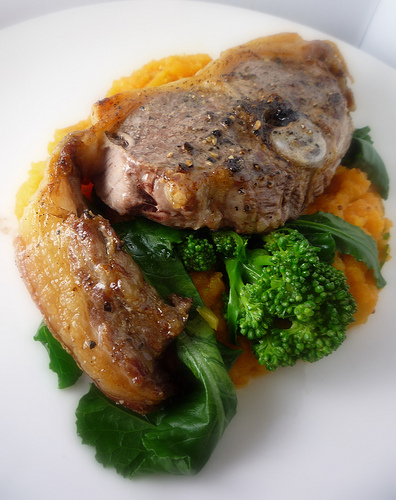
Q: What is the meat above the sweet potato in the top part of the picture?
A: The meat is a steak.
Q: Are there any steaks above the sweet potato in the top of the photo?
A: Yes, there is a steak above the sweet potato.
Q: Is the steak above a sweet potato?
A: Yes, the steak is above a sweet potato.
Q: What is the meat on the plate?
A: The meat is a steak.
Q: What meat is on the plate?
A: The meat is a steak.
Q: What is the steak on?
A: The steak is on the plate.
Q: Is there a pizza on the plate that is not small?
A: No, there is a steak on the plate.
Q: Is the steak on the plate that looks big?
A: Yes, the steak is on the plate.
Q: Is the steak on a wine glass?
A: No, the steak is on the plate.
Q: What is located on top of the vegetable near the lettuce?
A: The steak is on top of the broccoli.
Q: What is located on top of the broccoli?
A: The steak is on top of the broccoli.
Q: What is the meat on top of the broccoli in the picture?
A: The meat is a steak.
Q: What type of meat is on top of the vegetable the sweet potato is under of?
A: The meat is a steak.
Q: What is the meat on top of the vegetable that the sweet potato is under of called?
A: The meat is a steak.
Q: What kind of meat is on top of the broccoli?
A: The meat is a steak.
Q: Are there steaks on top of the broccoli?
A: Yes, there is a steak on top of the broccoli.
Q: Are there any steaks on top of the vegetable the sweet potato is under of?
A: Yes, there is a steak on top of the broccoli.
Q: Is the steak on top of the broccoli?
A: Yes, the steak is on top of the broccoli.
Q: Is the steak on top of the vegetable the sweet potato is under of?
A: Yes, the steak is on top of the broccoli.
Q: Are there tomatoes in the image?
A: No, there are no tomatoes.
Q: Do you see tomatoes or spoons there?
A: No, there are no tomatoes or spoons.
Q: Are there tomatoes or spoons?
A: No, there are no tomatoes or spoons.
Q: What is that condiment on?
A: The condiment is on the broccoli.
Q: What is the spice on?
A: The condiment is on the broccoli.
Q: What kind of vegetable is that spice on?
A: The spice is on the broccoli.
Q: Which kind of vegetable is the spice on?
A: The spice is on the broccoli.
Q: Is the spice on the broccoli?
A: Yes, the spice is on the broccoli.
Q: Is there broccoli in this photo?
A: Yes, there is broccoli.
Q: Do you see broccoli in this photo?
A: Yes, there is broccoli.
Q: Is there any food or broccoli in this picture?
A: Yes, there is broccoli.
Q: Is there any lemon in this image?
A: No, there are no lemons.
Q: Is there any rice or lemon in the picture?
A: No, there are no lemons or rice.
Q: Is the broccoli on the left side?
A: No, the broccoli is on the right of the image.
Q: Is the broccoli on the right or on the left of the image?
A: The broccoli is on the right of the image.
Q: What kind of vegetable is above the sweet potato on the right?
A: The vegetable is broccoli.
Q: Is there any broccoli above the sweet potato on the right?
A: Yes, there is broccoli above the sweet potato.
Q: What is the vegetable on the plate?
A: The vegetable is broccoli.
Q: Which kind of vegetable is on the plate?
A: The vegetable is broccoli.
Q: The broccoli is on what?
A: The broccoli is on the plate.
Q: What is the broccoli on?
A: The broccoli is on the plate.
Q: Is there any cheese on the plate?
A: No, there is broccoli on the plate.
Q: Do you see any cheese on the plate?
A: No, there is broccoli on the plate.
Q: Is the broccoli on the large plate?
A: Yes, the broccoli is on the plate.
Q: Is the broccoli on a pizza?
A: No, the broccoli is on the plate.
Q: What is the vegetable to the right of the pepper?
A: The vegetable is broccoli.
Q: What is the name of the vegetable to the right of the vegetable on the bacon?
A: The vegetable is broccoli.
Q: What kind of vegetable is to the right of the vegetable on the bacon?
A: The vegetable is broccoli.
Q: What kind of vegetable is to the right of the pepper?
A: The vegetable is broccoli.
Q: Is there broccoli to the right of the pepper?
A: Yes, there is broccoli to the right of the pepper.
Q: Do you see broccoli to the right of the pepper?
A: Yes, there is broccoli to the right of the pepper.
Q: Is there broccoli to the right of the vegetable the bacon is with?
A: Yes, there is broccoli to the right of the pepper.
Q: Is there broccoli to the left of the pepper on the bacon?
A: No, the broccoli is to the right of the pepper.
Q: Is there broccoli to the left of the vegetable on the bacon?
A: No, the broccoli is to the right of the pepper.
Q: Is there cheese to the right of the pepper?
A: No, there is broccoli to the right of the pepper.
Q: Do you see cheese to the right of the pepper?
A: No, there is broccoli to the right of the pepper.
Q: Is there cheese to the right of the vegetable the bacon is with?
A: No, there is broccoli to the right of the pepper.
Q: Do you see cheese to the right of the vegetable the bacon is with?
A: No, there is broccoli to the right of the pepper.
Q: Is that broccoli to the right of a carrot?
A: No, the broccoli is to the right of the pepper.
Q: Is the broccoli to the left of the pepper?
A: No, the broccoli is to the right of the pepper.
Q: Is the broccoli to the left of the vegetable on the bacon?
A: No, the broccoli is to the right of the pepper.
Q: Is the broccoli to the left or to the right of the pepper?
A: The broccoli is to the right of the pepper.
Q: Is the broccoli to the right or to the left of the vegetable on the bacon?
A: The broccoli is to the right of the pepper.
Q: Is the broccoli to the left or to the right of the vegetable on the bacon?
A: The broccoli is to the right of the pepper.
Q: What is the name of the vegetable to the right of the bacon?
A: The vegetable is broccoli.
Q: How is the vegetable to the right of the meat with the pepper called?
A: The vegetable is broccoli.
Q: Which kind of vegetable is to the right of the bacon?
A: The vegetable is broccoli.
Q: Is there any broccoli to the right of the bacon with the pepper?
A: Yes, there is broccoli to the right of the bacon.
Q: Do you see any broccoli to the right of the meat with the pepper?
A: Yes, there is broccoli to the right of the bacon.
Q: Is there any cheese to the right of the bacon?
A: No, there is broccoli to the right of the bacon.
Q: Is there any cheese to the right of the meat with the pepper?
A: No, there is broccoli to the right of the bacon.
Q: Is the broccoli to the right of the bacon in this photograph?
A: Yes, the broccoli is to the right of the bacon.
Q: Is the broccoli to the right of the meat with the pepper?
A: Yes, the broccoli is to the right of the bacon.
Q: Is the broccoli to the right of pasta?
A: No, the broccoli is to the right of the bacon.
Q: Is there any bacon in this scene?
A: Yes, there is bacon.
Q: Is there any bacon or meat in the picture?
A: Yes, there is bacon.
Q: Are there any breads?
A: No, there are no breads.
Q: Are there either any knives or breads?
A: No, there are no breads or knives.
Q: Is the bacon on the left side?
A: Yes, the bacon is on the left of the image.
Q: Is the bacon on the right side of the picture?
A: No, the bacon is on the left of the image.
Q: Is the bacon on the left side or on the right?
A: The bacon is on the left of the image.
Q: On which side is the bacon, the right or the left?
A: The bacon is on the left of the image.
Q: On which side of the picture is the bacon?
A: The bacon is on the left of the image.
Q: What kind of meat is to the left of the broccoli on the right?
A: The meat is bacon.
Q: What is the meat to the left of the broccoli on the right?
A: The meat is bacon.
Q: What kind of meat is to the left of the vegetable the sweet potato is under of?
A: The meat is bacon.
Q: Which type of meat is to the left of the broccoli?
A: The meat is bacon.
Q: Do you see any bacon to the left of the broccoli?
A: Yes, there is bacon to the left of the broccoli.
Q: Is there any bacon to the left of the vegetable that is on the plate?
A: Yes, there is bacon to the left of the broccoli.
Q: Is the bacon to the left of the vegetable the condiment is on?
A: Yes, the bacon is to the left of the broccoli.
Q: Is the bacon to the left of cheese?
A: No, the bacon is to the left of the broccoli.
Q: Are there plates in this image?
A: Yes, there is a plate.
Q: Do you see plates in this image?
A: Yes, there is a plate.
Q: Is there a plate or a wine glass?
A: Yes, there is a plate.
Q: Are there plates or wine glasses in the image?
A: Yes, there is a plate.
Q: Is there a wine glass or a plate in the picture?
A: Yes, there is a plate.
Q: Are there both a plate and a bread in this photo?
A: No, there is a plate but no breads.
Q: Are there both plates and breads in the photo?
A: No, there is a plate but no breads.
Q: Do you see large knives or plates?
A: Yes, there is a large plate.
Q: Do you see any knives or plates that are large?
A: Yes, the plate is large.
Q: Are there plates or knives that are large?
A: Yes, the plate is large.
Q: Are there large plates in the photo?
A: Yes, there is a large plate.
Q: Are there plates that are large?
A: Yes, there is a plate that is large.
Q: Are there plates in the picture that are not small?
A: Yes, there is a large plate.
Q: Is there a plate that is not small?
A: Yes, there is a large plate.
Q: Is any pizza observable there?
A: No, there are no pizzas.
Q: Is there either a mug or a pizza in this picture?
A: No, there are no pizzas or mugs.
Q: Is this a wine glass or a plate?
A: This is a plate.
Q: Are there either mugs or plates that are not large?
A: No, there is a plate but it is large.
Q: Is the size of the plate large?
A: Yes, the plate is large.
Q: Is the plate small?
A: No, the plate is large.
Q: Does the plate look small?
A: No, the plate is large.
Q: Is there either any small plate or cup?
A: No, there is a plate but it is large.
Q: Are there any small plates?
A: No, there is a plate but it is large.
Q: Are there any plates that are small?
A: No, there is a plate but it is large.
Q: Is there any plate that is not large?
A: No, there is a plate but it is large.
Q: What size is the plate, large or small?
A: The plate is large.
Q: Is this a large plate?
A: Yes, this is a large plate.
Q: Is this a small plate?
A: No, this is a large plate.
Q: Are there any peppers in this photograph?
A: Yes, there is a pepper.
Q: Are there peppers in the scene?
A: Yes, there is a pepper.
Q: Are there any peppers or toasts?
A: Yes, there is a pepper.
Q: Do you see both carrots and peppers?
A: No, there is a pepper but no carrots.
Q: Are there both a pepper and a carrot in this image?
A: No, there is a pepper but no carrots.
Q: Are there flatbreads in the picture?
A: No, there are no flatbreads.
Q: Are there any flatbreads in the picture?
A: No, there are no flatbreads.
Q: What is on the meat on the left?
A: The pepper is on the bacon.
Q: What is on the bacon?
A: The pepper is on the bacon.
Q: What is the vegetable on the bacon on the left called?
A: The vegetable is a pepper.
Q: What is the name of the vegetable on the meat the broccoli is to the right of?
A: The vegetable is a pepper.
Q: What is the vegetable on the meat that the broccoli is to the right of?
A: The vegetable is a pepper.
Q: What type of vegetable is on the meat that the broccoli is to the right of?
A: The vegetable is a pepper.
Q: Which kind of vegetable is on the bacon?
A: The vegetable is a pepper.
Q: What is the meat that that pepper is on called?
A: The meat is bacon.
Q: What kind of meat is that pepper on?
A: The pepper is on the bacon.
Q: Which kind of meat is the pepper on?
A: The pepper is on the bacon.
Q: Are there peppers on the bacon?
A: Yes, there is a pepper on the bacon.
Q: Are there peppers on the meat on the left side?
A: Yes, there is a pepper on the bacon.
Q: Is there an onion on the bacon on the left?
A: No, there is a pepper on the bacon.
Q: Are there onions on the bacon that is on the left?
A: No, there is a pepper on the bacon.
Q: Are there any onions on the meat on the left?
A: No, there is a pepper on the bacon.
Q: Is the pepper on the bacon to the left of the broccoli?
A: Yes, the pepper is on the bacon.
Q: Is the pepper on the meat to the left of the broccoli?
A: Yes, the pepper is on the bacon.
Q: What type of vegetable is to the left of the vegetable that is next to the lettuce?
A: The vegetable is a pepper.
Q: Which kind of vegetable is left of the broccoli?
A: The vegetable is a pepper.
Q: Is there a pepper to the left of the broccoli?
A: Yes, there is a pepper to the left of the broccoli.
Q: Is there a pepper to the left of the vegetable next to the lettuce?
A: Yes, there is a pepper to the left of the broccoli.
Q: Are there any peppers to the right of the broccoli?
A: No, the pepper is to the left of the broccoli.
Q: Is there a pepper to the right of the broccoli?
A: No, the pepper is to the left of the broccoli.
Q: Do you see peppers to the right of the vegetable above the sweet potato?
A: No, the pepper is to the left of the broccoli.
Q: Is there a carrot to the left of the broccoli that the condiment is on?
A: No, there is a pepper to the left of the broccoli.